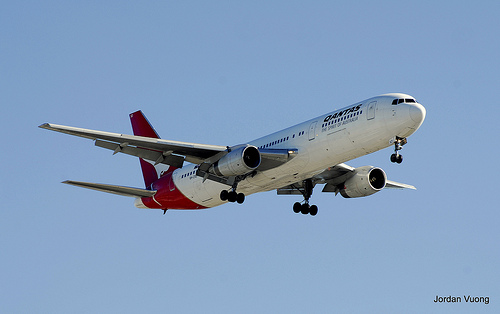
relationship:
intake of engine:
[243, 146, 260, 168] [206, 145, 261, 177]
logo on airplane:
[321, 103, 362, 123] [38, 94, 426, 216]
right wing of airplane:
[316, 162, 416, 190] [38, 94, 426, 216]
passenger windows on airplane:
[258, 135, 290, 148] [38, 94, 426, 216]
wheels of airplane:
[292, 202, 317, 216] [38, 94, 426, 216]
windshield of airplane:
[390, 98, 417, 106] [38, 94, 426, 216]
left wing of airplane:
[38, 123, 298, 172] [38, 94, 426, 216]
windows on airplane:
[179, 170, 194, 177] [38, 94, 426, 216]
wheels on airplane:
[389, 152, 404, 163] [38, 94, 426, 216]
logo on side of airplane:
[321, 103, 362, 123] [38, 94, 426, 216]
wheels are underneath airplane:
[219, 189, 244, 205] [38, 94, 426, 216]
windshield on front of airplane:
[390, 98, 417, 106] [38, 94, 426, 216]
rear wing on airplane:
[60, 179, 155, 197] [38, 94, 426, 216]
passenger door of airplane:
[307, 121, 316, 140] [38, 94, 426, 216]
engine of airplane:
[339, 166, 387, 197] [38, 94, 426, 216]